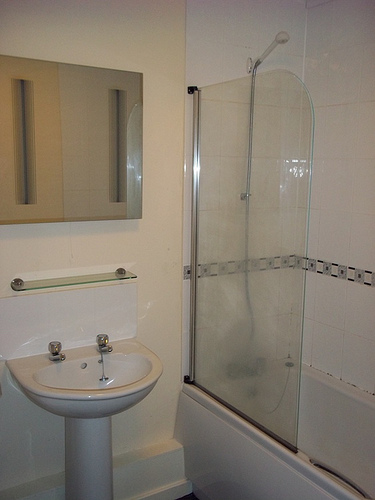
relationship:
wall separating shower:
[183, 69, 314, 453] [171, 11, 371, 498]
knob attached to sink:
[48, 340, 62, 354] [16, 335, 160, 399]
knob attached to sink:
[96, 334, 107, 346] [16, 335, 160, 399]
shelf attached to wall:
[8, 265, 138, 292] [1, 15, 185, 493]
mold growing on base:
[301, 359, 373, 396] [293, 358, 374, 406]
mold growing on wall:
[301, 359, 373, 396] [293, 0, 373, 407]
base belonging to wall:
[293, 358, 374, 406] [293, 0, 373, 407]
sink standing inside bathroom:
[5, 335, 164, 420] [5, 42, 367, 482]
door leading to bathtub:
[188, 67, 312, 454] [175, 352, 375, 498]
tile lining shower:
[320, 257, 333, 276] [218, 27, 312, 338]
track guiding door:
[182, 381, 364, 498] [170, 65, 362, 466]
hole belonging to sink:
[79, 360, 87, 371] [5, 335, 164, 420]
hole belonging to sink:
[97, 359, 103, 364] [5, 335, 164, 420]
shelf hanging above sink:
[8, 265, 138, 292] [5, 335, 164, 420]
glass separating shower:
[183, 67, 326, 452] [171, 11, 371, 498]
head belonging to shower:
[261, 22, 295, 52] [239, 29, 294, 341]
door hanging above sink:
[1, 53, 68, 226] [3, 270, 187, 441]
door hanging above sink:
[55, 59, 143, 222] [3, 270, 187, 441]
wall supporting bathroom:
[1, 15, 185, 493] [2, 1, 368, 491]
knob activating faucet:
[46, 339, 64, 355] [47, 341, 66, 362]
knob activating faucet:
[96, 334, 110, 345] [94, 340, 117, 356]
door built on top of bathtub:
[188, 67, 312, 454] [172, 356, 363, 497]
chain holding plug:
[251, 368, 291, 414] [283, 361, 296, 369]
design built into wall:
[319, 261, 332, 275] [0, 12, 182, 335]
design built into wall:
[307, 258, 317, 271] [0, 12, 182, 335]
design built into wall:
[280, 252, 290, 269] [0, 12, 182, 335]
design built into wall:
[235, 259, 245, 275] [0, 12, 182, 335]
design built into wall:
[184, 264, 194, 278] [0, 12, 182, 335]